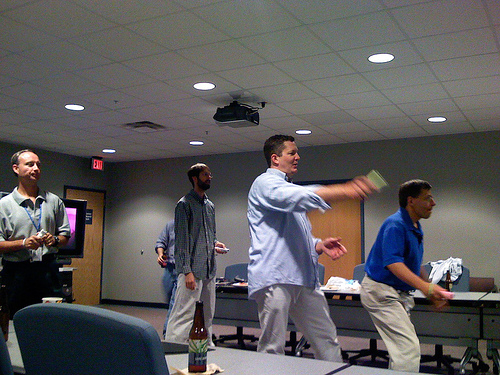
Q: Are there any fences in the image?
A: No, there are no fences.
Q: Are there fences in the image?
A: No, there are no fences.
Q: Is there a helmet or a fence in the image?
A: No, there are no fences or helmets.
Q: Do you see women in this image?
A: No, there are no women.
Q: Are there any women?
A: No, there are no women.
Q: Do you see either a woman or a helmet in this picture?
A: No, there are no women or helmets.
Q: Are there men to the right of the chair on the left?
A: Yes, there is a man to the right of the chair.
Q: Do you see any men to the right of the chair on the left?
A: Yes, there is a man to the right of the chair.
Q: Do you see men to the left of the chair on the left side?
A: No, the man is to the right of the chair.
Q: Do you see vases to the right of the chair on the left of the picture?
A: No, there is a man to the right of the chair.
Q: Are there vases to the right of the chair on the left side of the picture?
A: No, there is a man to the right of the chair.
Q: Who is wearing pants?
A: The man is wearing pants.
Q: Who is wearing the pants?
A: The man is wearing pants.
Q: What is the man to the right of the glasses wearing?
A: The man is wearing trousers.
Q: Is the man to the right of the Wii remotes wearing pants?
A: Yes, the man is wearing pants.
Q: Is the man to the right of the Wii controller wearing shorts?
A: No, the man is wearing pants.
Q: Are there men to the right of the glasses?
A: Yes, there is a man to the right of the glasses.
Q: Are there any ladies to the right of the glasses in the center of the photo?
A: No, there is a man to the right of the glasses.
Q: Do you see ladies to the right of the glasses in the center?
A: No, there is a man to the right of the glasses.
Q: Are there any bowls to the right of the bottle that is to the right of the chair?
A: No, there is a man to the right of the bottle.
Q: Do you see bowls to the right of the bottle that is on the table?
A: No, there is a man to the right of the bottle.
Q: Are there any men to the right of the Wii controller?
A: Yes, there is a man to the right of the Wii controller.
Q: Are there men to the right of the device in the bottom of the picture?
A: Yes, there is a man to the right of the Wii controller.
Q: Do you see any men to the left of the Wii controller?
A: No, the man is to the right of the Wii controller.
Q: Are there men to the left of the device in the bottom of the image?
A: No, the man is to the right of the Wii controller.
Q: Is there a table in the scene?
A: Yes, there is a table.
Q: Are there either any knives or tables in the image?
A: Yes, there is a table.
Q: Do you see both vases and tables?
A: No, there is a table but no vases.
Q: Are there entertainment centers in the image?
A: No, there are no entertainment centers.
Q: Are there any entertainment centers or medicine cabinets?
A: No, there are no entertainment centers or medicine cabinets.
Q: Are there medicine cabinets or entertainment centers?
A: No, there are no entertainment centers or medicine cabinets.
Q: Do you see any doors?
A: Yes, there is a door.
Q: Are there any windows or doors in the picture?
A: Yes, there is a door.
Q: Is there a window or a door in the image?
A: Yes, there is a door.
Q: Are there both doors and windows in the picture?
A: No, there is a door but no windows.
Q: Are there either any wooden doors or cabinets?
A: Yes, there is a wood door.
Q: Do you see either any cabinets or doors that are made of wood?
A: Yes, the door is made of wood.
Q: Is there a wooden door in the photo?
A: Yes, there is a wood door.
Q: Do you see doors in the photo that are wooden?
A: Yes, there is a door that is wooden.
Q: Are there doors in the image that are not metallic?
A: Yes, there is a wooden door.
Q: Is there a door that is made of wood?
A: Yes, there is a door that is made of wood.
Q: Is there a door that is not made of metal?
A: Yes, there is a door that is made of wood.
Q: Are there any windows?
A: No, there are no windows.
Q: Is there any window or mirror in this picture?
A: No, there are no windows or mirrors.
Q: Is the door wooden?
A: Yes, the door is wooden.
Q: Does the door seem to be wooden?
A: Yes, the door is wooden.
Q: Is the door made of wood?
A: Yes, the door is made of wood.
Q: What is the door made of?
A: The door is made of wood.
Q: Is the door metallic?
A: No, the door is wooden.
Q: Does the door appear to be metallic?
A: No, the door is wooden.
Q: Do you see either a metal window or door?
A: No, there is a door but it is wooden.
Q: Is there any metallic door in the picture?
A: No, there is a door but it is wooden.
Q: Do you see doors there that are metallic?
A: No, there is a door but it is wooden.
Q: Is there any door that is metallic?
A: No, there is a door but it is wooden.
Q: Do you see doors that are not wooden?
A: No, there is a door but it is wooden.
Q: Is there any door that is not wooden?
A: No, there is a door but it is wooden.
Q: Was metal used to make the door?
A: No, the door is made of wood.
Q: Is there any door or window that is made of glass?
A: No, there is a door but it is made of wood.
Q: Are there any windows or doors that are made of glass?
A: No, there is a door but it is made of wood.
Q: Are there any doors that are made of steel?
A: No, there is a door but it is made of wood.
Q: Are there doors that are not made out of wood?
A: No, there is a door but it is made of wood.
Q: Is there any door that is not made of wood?
A: No, there is a door but it is made of wood.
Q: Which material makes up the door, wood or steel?
A: The door is made of wood.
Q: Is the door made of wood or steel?
A: The door is made of wood.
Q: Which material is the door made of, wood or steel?
A: The door is made of wood.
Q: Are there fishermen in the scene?
A: No, there are no fishermen.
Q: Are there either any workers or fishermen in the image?
A: No, there are no fishermen or workers.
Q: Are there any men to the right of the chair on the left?
A: Yes, there is a man to the right of the chair.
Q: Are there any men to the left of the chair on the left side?
A: No, the man is to the right of the chair.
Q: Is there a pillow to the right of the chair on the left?
A: No, there is a man to the right of the chair.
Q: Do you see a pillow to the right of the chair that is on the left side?
A: No, there is a man to the right of the chair.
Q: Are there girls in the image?
A: No, there are no girls.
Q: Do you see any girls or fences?
A: No, there are no girls or fences.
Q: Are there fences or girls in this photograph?
A: No, there are no girls or fences.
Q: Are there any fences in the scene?
A: No, there are no fences.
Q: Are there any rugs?
A: No, there are no rugs.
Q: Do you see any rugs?
A: No, there are no rugs.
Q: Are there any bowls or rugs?
A: No, there are no rugs or bowls.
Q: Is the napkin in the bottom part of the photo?
A: Yes, the napkin is in the bottom of the image.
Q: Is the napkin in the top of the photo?
A: No, the napkin is in the bottom of the image.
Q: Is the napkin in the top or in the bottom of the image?
A: The napkin is in the bottom of the image.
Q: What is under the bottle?
A: The napkin is under the bottle.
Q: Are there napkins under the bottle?
A: Yes, there is a napkin under the bottle.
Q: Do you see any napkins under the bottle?
A: Yes, there is a napkin under the bottle.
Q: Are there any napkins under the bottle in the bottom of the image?
A: Yes, there is a napkin under the bottle.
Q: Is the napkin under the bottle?
A: Yes, the napkin is under the bottle.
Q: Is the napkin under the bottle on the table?
A: Yes, the napkin is under the bottle.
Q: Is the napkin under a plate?
A: No, the napkin is under the bottle.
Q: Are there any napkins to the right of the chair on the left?
A: Yes, there is a napkin to the right of the chair.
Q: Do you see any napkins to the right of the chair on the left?
A: Yes, there is a napkin to the right of the chair.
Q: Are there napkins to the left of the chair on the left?
A: No, the napkin is to the right of the chair.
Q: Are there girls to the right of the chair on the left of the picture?
A: No, there is a napkin to the right of the chair.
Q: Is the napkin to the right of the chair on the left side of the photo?
A: Yes, the napkin is to the right of the chair.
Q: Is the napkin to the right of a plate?
A: No, the napkin is to the right of the chair.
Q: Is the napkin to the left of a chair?
A: No, the napkin is to the right of a chair.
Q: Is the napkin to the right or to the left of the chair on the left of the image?
A: The napkin is to the right of the chair.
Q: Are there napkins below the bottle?
A: Yes, there is a napkin below the bottle.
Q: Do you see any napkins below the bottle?
A: Yes, there is a napkin below the bottle.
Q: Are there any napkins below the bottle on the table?
A: Yes, there is a napkin below the bottle.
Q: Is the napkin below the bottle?
A: Yes, the napkin is below the bottle.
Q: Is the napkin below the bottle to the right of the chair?
A: Yes, the napkin is below the bottle.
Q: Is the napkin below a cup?
A: No, the napkin is below the bottle.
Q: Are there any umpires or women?
A: No, there are no women or umpires.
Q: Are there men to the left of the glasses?
A: Yes, there is a man to the left of the glasses.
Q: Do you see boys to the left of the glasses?
A: No, there is a man to the left of the glasses.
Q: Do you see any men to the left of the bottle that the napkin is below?
A: Yes, there is a man to the left of the bottle.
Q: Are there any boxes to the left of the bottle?
A: No, there is a man to the left of the bottle.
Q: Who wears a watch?
A: The man wears a watch.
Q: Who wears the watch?
A: The man wears a watch.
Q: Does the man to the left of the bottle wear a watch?
A: Yes, the man wears a watch.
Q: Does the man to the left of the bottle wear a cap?
A: No, the man wears a watch.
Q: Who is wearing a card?
A: The man is wearing a card.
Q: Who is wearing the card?
A: The man is wearing a card.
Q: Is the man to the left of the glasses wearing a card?
A: Yes, the man is wearing a card.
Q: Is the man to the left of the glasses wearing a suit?
A: No, the man is wearing a card.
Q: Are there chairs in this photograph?
A: Yes, there is a chair.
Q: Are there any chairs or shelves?
A: Yes, there is a chair.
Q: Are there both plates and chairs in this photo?
A: No, there is a chair but no plates.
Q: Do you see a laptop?
A: No, there are no laptops.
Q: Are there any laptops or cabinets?
A: No, there are no laptops or cabinets.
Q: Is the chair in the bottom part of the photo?
A: Yes, the chair is in the bottom of the image.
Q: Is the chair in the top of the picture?
A: No, the chair is in the bottom of the image.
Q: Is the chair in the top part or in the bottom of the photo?
A: The chair is in the bottom of the image.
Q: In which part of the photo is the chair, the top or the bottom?
A: The chair is in the bottom of the image.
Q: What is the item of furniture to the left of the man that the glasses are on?
A: The piece of furniture is a chair.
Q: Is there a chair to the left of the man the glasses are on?
A: Yes, there is a chair to the left of the man.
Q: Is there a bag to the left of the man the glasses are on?
A: No, there is a chair to the left of the man.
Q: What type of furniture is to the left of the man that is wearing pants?
A: The piece of furniture is a chair.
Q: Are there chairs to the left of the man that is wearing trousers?
A: Yes, there is a chair to the left of the man.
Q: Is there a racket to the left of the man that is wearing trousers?
A: No, there is a chair to the left of the man.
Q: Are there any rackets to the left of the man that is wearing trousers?
A: No, there is a chair to the left of the man.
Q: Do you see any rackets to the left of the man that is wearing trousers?
A: No, there is a chair to the left of the man.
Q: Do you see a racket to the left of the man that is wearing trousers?
A: No, there is a chair to the left of the man.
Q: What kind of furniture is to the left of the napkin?
A: The piece of furniture is a chair.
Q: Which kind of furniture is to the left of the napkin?
A: The piece of furniture is a chair.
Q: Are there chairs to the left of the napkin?
A: Yes, there is a chair to the left of the napkin.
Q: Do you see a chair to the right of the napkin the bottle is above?
A: No, the chair is to the left of the napkin.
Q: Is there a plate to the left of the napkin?
A: No, there is a chair to the left of the napkin.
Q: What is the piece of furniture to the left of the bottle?
A: The piece of furniture is a chair.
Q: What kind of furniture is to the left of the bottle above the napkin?
A: The piece of furniture is a chair.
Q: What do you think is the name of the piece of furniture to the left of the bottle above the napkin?
A: The piece of furniture is a chair.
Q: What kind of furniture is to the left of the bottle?
A: The piece of furniture is a chair.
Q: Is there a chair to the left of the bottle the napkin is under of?
A: Yes, there is a chair to the left of the bottle.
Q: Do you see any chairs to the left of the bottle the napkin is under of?
A: Yes, there is a chair to the left of the bottle.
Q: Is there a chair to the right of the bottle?
A: No, the chair is to the left of the bottle.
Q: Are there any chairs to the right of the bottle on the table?
A: No, the chair is to the left of the bottle.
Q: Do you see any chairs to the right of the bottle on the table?
A: No, the chair is to the left of the bottle.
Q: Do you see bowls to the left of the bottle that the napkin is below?
A: No, there is a chair to the left of the bottle.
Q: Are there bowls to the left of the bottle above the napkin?
A: No, there is a chair to the left of the bottle.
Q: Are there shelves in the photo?
A: No, there are no shelves.